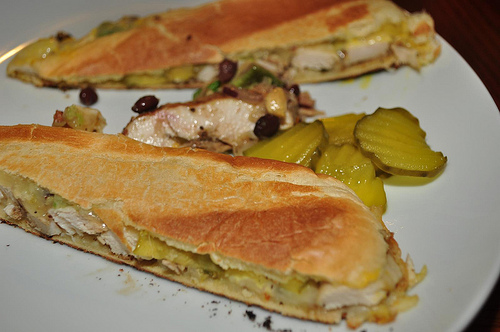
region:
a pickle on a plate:
[335, 145, 388, 197]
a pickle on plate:
[264, 130, 315, 175]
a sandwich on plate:
[47, 101, 408, 327]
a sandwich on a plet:
[43, 11, 465, 128]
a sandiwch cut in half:
[37, 24, 451, 306]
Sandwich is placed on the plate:
[3, 18, 473, 324]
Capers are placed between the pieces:
[63, 63, 287, 171]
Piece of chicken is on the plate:
[134, 75, 284, 173]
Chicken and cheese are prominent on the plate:
[132, 18, 454, 78]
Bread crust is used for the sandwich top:
[21, 85, 411, 319]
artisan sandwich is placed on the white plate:
[12, 10, 474, 322]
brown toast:
[215, 184, 320, 234]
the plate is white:
[78, 299, 120, 319]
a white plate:
[68, 305, 105, 321]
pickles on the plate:
[351, 113, 435, 163]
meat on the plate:
[196, 102, 246, 134]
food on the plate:
[73, 106, 438, 304]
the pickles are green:
[299, 120, 416, 175]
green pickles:
[352, 125, 424, 167]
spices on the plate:
[195, 300, 240, 317]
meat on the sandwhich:
[336, 288, 367, 305]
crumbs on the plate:
[103, 269, 161, 294]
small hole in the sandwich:
[331, 300, 351, 323]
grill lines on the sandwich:
[170, 157, 282, 249]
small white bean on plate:
[255, 85, 297, 120]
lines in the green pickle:
[357, 114, 417, 156]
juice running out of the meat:
[161, 121, 231, 152]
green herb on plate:
[231, 62, 278, 91]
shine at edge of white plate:
[3, 30, 28, 59]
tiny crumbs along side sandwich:
[181, 295, 256, 327]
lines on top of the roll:
[156, 195, 300, 259]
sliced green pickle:
[358, 103, 446, 186]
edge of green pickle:
[372, 154, 421, 177]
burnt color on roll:
[145, 205, 342, 247]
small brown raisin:
[121, 97, 173, 112]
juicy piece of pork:
[129, 100, 276, 147]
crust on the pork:
[173, 90, 215, 114]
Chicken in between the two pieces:
[68, 58, 348, 183]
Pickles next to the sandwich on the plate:
[253, 100, 464, 243]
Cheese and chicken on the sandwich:
[43, 18, 415, 330]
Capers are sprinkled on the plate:
[53, 53, 326, 178]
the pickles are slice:
[244, 106, 446, 211]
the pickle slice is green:
[354, 105, 447, 176]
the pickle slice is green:
[313, 141, 389, 213]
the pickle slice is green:
[243, 118, 326, 169]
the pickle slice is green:
[311, 112, 386, 176]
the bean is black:
[131, 94, 162, 114]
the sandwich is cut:
[1, 125, 428, 327]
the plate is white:
[1, 0, 499, 330]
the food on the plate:
[1, 0, 499, 330]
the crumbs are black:
[239, 304, 291, 329]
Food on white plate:
[22, 6, 444, 317]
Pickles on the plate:
[253, 100, 452, 209]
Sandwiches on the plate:
[15, 22, 437, 308]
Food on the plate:
[30, 20, 427, 312]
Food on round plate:
[17, 16, 423, 284]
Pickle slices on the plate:
[246, 98, 466, 206]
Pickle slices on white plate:
[254, 94, 440, 214]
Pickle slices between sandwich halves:
[247, 93, 439, 235]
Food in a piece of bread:
[11, 118, 403, 311]